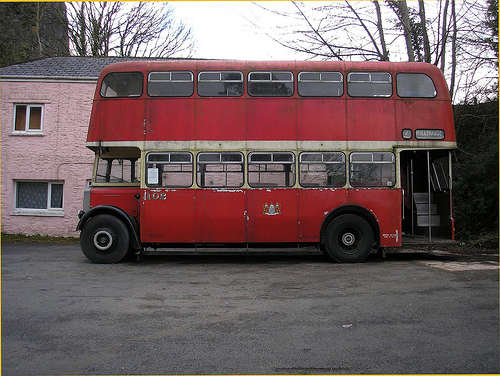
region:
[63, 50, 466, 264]
Bus on the road.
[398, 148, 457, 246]
door on the bus.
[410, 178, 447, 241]
steps on the bus.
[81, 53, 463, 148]
Upper level on the bus.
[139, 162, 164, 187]
Sign on the bus.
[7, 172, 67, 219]
Window in the building.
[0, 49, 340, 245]
Pink house behind the bus.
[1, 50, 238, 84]
Gray on the roof.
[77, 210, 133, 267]
Tire on the bus.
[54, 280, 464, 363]
The street is made of asphalt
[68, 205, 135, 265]
The front wheel of the tire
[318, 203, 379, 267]
The back wheel of the tire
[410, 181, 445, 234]
The stairs in the bus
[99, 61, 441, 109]
The windows on the side of the bus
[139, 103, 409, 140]
The bus is the color red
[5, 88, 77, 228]
The windows on the side of the building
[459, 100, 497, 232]
The leaves are the color green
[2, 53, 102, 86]
The roof of the house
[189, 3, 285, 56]
The sky is very clear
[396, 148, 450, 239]
the bus door is open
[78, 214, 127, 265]
black tire on the bus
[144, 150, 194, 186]
a passenger window on the bus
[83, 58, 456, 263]
a double decker bus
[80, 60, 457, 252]
the bus is red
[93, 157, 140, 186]
the driver's window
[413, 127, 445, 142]
location sign on the bus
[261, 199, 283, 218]
logo painted on the side of the bus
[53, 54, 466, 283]
a red and white bus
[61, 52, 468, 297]
a double decker bus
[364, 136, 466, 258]
an open doorway on bus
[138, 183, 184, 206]
a number on side of bus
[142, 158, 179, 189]
a white paper in the widnow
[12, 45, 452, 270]
a pink building by bus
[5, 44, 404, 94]
a gray roof on building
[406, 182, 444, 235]
stairs on the bus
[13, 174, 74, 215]
a gray curtain in window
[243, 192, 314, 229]
a design on side of bus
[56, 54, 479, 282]
A red old double decker bus.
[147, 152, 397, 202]
Windows on the bus.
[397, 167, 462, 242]
Door to the bus.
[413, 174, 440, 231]
Stair on the bus.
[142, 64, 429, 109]
Windows on top of the upper level.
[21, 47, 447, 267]
Bus is parked in front of the pink building.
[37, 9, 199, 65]
Trees behind the building.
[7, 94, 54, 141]
Window on the pink building.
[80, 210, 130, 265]
A wheel on the bus.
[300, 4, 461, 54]
The tree does not have any leaves.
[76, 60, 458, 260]
the bus is a double decker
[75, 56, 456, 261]
the bus is red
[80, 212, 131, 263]
the tire is black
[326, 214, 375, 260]
the tire is black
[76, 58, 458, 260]
the bus is old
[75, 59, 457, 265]
the bus is dirty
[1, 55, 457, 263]
the bus in front of the building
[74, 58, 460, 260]
the bus is parked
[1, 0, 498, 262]
the bare branches around the bus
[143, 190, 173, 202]
number 102 on a bus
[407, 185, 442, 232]
steps on a bus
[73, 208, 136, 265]
front tire of a bus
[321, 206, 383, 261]
back tire of a bus